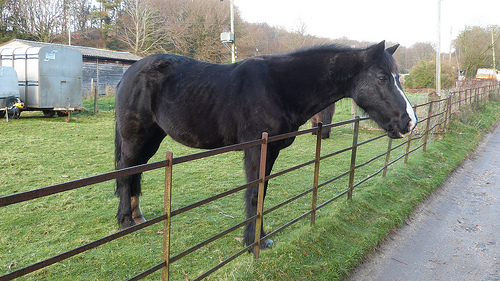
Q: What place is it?
A: It is a field.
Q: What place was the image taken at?
A: It was taken at the field.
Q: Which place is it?
A: It is a field.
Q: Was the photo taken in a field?
A: Yes, it was taken in a field.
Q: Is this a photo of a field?
A: Yes, it is showing a field.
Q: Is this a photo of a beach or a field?
A: It is showing a field.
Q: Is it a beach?
A: No, it is a field.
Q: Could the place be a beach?
A: No, it is a field.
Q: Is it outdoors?
A: Yes, it is outdoors.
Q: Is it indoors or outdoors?
A: It is outdoors.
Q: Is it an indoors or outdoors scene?
A: It is outdoors.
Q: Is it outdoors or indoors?
A: It is outdoors.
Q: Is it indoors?
A: No, it is outdoors.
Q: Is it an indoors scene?
A: No, it is outdoors.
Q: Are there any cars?
A: No, there are no cars.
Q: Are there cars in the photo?
A: No, there are no cars.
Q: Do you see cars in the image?
A: No, there are no cars.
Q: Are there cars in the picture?
A: No, there are no cars.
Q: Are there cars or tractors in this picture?
A: No, there are no cars or tractors.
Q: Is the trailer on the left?
A: Yes, the trailer is on the left of the image.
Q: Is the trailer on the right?
A: No, the trailer is on the left of the image.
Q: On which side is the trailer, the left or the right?
A: The trailer is on the left of the image.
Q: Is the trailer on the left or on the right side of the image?
A: The trailer is on the left of the image.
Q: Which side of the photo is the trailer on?
A: The trailer is on the left of the image.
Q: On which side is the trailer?
A: The trailer is on the left of the image.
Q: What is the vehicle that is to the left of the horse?
A: The vehicle is a trailer.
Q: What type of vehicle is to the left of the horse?
A: The vehicle is a trailer.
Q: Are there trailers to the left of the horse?
A: Yes, there is a trailer to the left of the horse.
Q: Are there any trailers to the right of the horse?
A: No, the trailer is to the left of the horse.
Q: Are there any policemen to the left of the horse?
A: No, there is a trailer to the left of the horse.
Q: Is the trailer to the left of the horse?
A: Yes, the trailer is to the left of the horse.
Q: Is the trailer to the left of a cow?
A: No, the trailer is to the left of the horse.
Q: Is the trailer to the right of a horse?
A: No, the trailer is to the left of a horse.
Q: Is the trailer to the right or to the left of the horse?
A: The trailer is to the left of the horse.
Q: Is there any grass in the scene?
A: Yes, there is grass.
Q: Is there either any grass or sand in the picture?
A: Yes, there is grass.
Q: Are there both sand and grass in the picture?
A: No, there is grass but no sand.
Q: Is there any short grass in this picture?
A: Yes, there is short grass.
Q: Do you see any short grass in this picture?
A: Yes, there is short grass.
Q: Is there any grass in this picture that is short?
A: Yes, there is grass that is short.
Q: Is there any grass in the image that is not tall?
A: Yes, there is short grass.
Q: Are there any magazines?
A: No, there are no magazines.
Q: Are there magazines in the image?
A: No, there are no magazines.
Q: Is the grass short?
A: Yes, the grass is short.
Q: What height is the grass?
A: The grass is short.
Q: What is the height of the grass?
A: The grass is short.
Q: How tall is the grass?
A: The grass is short.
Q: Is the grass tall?
A: No, the grass is short.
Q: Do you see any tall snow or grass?
A: No, there is grass but it is short.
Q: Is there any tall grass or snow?
A: No, there is grass but it is short.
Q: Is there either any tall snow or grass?
A: No, there is grass but it is short.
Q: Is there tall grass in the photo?
A: No, there is grass but it is short.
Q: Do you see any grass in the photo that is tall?
A: No, there is grass but it is short.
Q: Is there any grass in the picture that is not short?
A: No, there is grass but it is short.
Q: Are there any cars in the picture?
A: No, there are no cars.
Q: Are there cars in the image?
A: No, there are no cars.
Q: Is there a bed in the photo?
A: No, there are no beds.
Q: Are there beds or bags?
A: No, there are no beds or bags.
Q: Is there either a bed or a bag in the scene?
A: No, there are no beds or bags.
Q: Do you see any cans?
A: No, there are no cans.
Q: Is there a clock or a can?
A: No, there are no cans or clocks.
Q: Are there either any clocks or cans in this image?
A: No, there are no cans or clocks.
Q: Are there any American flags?
A: No, there are no American flags.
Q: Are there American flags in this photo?
A: No, there are no American flags.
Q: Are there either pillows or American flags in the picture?
A: No, there are no American flags or pillows.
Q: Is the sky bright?
A: Yes, the sky is bright.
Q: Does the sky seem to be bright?
A: Yes, the sky is bright.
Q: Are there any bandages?
A: No, there are no bandages.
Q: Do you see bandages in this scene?
A: No, there are no bandages.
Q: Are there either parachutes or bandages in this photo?
A: No, there are no bandages or parachutes.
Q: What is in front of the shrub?
A: The pole is in front of the shrub.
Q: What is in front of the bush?
A: The pole is in front of the shrub.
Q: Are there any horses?
A: Yes, there is a horse.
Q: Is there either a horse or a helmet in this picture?
A: Yes, there is a horse.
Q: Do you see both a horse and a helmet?
A: No, there is a horse but no helmets.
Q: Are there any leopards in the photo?
A: No, there are no leopards.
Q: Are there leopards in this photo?
A: No, there are no leopards.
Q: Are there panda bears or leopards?
A: No, there are no leopards or panda bears.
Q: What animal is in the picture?
A: The animal is a horse.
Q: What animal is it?
A: The animal is a horse.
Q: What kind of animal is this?
A: This is a horse.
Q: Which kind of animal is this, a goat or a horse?
A: This is a horse.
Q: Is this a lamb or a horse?
A: This is a horse.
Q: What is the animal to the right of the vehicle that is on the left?
A: The animal is a horse.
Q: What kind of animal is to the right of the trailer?
A: The animal is a horse.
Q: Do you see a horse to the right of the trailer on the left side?
A: Yes, there is a horse to the right of the trailer.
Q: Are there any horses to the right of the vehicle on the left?
A: Yes, there is a horse to the right of the trailer.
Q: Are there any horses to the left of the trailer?
A: No, the horse is to the right of the trailer.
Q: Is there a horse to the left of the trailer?
A: No, the horse is to the right of the trailer.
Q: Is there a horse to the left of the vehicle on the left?
A: No, the horse is to the right of the trailer.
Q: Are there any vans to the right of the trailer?
A: No, there is a horse to the right of the trailer.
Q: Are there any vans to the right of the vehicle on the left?
A: No, there is a horse to the right of the trailer.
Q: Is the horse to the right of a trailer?
A: Yes, the horse is to the right of a trailer.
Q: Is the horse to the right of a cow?
A: No, the horse is to the right of a trailer.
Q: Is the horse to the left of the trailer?
A: No, the horse is to the right of the trailer.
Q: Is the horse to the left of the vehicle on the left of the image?
A: No, the horse is to the right of the trailer.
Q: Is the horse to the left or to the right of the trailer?
A: The horse is to the right of the trailer.